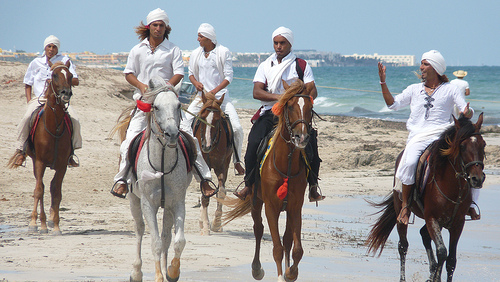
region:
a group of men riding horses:
[8, 8, 488, 280]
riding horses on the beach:
[7, 8, 491, 280]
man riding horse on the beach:
[366, 47, 491, 279]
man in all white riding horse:
[6, 34, 83, 236]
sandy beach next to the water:
[7, 61, 491, 277]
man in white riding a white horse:
[109, 9, 191, 280]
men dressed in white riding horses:
[8, 8, 487, 279]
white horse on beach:
[116, 84, 188, 279]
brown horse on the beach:
[21, 57, 78, 239]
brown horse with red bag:
[216, 77, 315, 279]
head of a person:
[413, 51, 453, 82]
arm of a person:
[359, 71, 419, 109]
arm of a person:
[452, 89, 482, 147]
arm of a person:
[242, 68, 296, 108]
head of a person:
[190, 12, 215, 53]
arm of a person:
[209, 71, 236, 95]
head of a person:
[129, 3, 180, 53]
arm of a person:
[109, 56, 150, 94]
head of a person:
[25, 38, 75, 72]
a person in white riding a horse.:
[366, 39, 489, 280]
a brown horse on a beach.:
[214, 73, 320, 281]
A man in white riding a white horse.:
[106, 7, 222, 198]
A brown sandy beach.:
[1, 58, 498, 279]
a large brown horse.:
[3, 58, 91, 238]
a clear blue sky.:
[0, 2, 496, 64]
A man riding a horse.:
[141, 2, 176, 32]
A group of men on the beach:
[1, 0, 490, 280]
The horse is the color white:
[127, 88, 202, 278]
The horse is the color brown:
[422, 126, 484, 269]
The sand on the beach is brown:
[24, 224, 114, 280]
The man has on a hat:
[138, 7, 176, 34]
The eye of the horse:
[171, 96, 185, 114]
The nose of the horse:
[158, 123, 185, 143]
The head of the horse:
[146, 78, 196, 151]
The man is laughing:
[370, 44, 478, 131]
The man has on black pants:
[242, 105, 325, 192]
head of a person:
[420, 45, 458, 85]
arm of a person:
[370, 62, 411, 109]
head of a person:
[267, 21, 308, 53]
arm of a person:
[250, 79, 301, 106]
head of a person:
[193, 25, 220, 49]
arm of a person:
[183, 65, 214, 96]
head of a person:
[140, 6, 182, 47]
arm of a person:
[117, 52, 157, 96]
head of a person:
[40, 19, 61, 64]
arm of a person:
[6, 65, 40, 110]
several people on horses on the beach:
[10, 21, 487, 254]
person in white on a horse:
[366, 28, 483, 270]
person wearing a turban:
[258, 13, 321, 187]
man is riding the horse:
[113, 5, 220, 198]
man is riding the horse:
[8, 32, 85, 167]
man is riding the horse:
[234, 26, 326, 203]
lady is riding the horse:
[377, 47, 479, 225]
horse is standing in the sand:
[118, 77, 190, 279]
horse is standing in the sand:
[28, 56, 73, 235]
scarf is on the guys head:
[271, 25, 293, 47]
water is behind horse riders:
[102, 64, 498, 127]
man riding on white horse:
[112, 0, 222, 276]